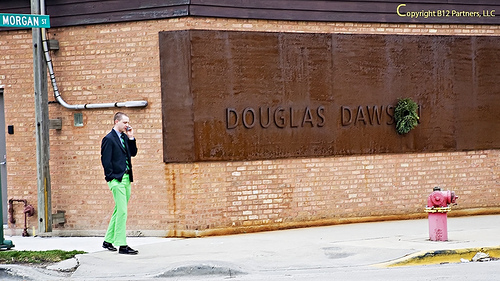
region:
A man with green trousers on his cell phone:
[88, 105, 150, 263]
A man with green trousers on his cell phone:
[91, 111, 146, 263]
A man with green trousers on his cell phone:
[95, 108, 146, 260]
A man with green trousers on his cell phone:
[92, 103, 144, 263]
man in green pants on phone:
[98, 104, 149, 247]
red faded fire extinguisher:
[417, 173, 460, 238]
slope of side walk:
[141, 250, 238, 277]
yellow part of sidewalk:
[418, 244, 492, 262]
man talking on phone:
[103, 111, 132, 137]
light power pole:
[26, 0, 65, 231]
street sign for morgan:
[0, 10, 70, 47]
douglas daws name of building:
[219, 92, 434, 145]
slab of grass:
[3, 248, 79, 264]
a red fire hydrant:
[425, 177, 466, 244]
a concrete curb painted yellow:
[393, 243, 493, 278]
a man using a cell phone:
[115, 104, 143, 139]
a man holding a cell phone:
[115, 119, 138, 141]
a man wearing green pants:
[105, 175, 131, 245]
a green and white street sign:
[0, 13, 60, 28]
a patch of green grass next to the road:
[0, 235, 90, 276]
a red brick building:
[227, 10, 399, 227]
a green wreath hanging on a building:
[385, 90, 422, 142]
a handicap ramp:
[229, 240, 415, 280]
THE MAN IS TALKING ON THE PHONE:
[75, 105, 158, 257]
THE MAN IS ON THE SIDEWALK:
[78, 104, 157, 264]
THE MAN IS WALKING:
[93, 103, 145, 264]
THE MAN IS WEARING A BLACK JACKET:
[100, 117, 145, 178]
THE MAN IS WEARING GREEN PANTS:
[96, 171, 138, 241]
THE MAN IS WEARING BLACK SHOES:
[95, 235, 140, 260]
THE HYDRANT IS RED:
[415, 175, 470, 252]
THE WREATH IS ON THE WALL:
[387, 97, 429, 142]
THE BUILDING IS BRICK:
[0, 7, 497, 233]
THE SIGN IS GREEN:
[0, 8, 55, 37]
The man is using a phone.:
[119, 121, 134, 138]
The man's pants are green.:
[101, 182, 130, 241]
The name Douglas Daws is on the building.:
[226, 104, 396, 128]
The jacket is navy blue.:
[103, 142, 119, 169]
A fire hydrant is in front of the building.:
[426, 187, 455, 240]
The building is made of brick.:
[69, 35, 154, 97]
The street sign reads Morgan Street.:
[1, 14, 52, 25]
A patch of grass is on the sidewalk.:
[0, 251, 61, 261]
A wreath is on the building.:
[393, 100, 422, 134]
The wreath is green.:
[393, 97, 421, 133]